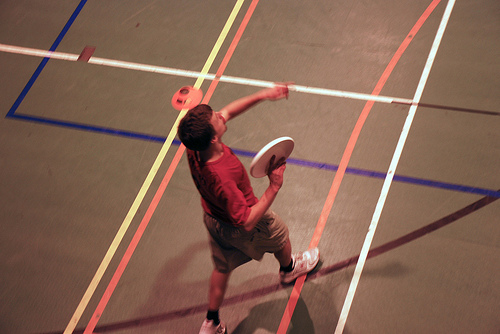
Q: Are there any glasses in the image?
A: No, there are no glasses.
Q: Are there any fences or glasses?
A: No, there are no glasses or fences.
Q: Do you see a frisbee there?
A: Yes, there is a frisbee.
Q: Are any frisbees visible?
A: Yes, there is a frisbee.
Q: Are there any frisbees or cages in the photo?
A: Yes, there is a frisbee.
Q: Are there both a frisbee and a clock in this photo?
A: No, there is a frisbee but no clocks.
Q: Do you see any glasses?
A: No, there are no glasses.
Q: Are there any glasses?
A: No, there are no glasses.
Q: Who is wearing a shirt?
A: The man is wearing a shirt.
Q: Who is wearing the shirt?
A: The man is wearing a shirt.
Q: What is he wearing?
A: The man is wearing a shirt.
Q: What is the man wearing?
A: The man is wearing a shirt.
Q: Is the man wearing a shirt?
A: Yes, the man is wearing a shirt.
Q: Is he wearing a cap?
A: No, the man is wearing a shirt.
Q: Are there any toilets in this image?
A: No, there are no toilets.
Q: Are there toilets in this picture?
A: No, there are no toilets.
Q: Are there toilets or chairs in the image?
A: No, there are no toilets or chairs.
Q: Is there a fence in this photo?
A: No, there are no fences.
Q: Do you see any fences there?
A: No, there are no fences.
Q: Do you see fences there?
A: No, there are no fences.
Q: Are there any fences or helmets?
A: No, there are no fences or helmets.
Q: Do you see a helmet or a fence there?
A: No, there are no fences or helmets.